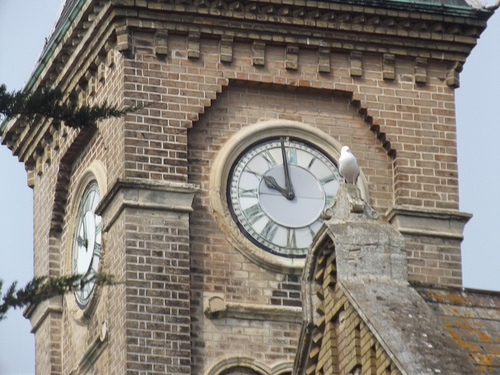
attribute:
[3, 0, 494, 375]
tower — made of bricks, brick, large, clock tower, decorated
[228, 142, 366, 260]
clock — white-faced, white, like a watch, lined, large, white circle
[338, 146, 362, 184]
dove — white, like seagull, grey, on tip of roof, sitting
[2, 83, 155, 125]
branch — green, from tree, hanging, long, in foreground, small, extending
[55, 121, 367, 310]
2 clocks — on building, inlaid in tower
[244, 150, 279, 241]
numbers — roman numerals, in white circle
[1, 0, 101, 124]
border — green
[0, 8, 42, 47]
sky — showing cloudy day, cloudy, overcast, blue, colored blue, colored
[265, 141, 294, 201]
hands — black, wrought iron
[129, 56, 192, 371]
wall — made of bricks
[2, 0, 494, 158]
roof — marked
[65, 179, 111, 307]
clock face — angled slightly, colored white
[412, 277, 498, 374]
roof — old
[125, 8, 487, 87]
brick edgework — sticking out, dark, white, jagged, smooth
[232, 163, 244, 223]
clock lines — circular, grey, marking minutes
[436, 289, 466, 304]
moss — rust colored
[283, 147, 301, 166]
xii — iodized